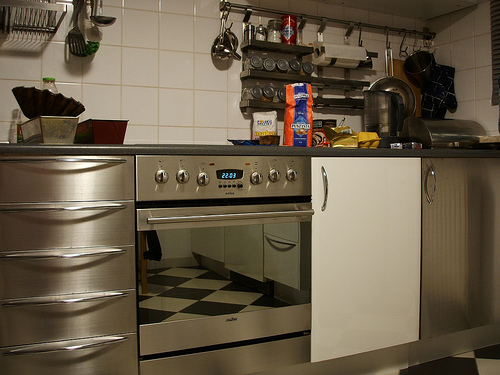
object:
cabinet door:
[420, 158, 499, 340]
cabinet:
[0, 143, 500, 375]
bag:
[283, 83, 314, 148]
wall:
[0, 0, 500, 145]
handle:
[321, 166, 328, 212]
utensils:
[89, 0, 115, 27]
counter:
[0, 143, 500, 158]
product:
[357, 130, 381, 149]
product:
[323, 126, 359, 150]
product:
[312, 129, 331, 148]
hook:
[409, 30, 421, 53]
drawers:
[0, 244, 137, 300]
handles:
[0, 291, 130, 307]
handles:
[0, 203, 127, 212]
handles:
[0, 248, 128, 261]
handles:
[0, 156, 127, 163]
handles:
[0, 335, 128, 354]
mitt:
[421, 65, 458, 120]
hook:
[428, 32, 437, 54]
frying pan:
[368, 47, 417, 120]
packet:
[227, 139, 278, 146]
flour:
[252, 110, 278, 140]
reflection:
[141, 287, 223, 304]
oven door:
[168, 282, 218, 307]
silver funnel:
[211, 31, 242, 61]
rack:
[217, 0, 437, 54]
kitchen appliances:
[210, 0, 457, 113]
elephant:
[307, 152, 428, 367]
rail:
[219, 0, 436, 40]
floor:
[460, 354, 500, 374]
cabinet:
[309, 155, 421, 364]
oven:
[135, 155, 311, 233]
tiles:
[117, 44, 199, 101]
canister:
[281, 15, 297, 45]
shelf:
[240, 69, 371, 92]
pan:
[368, 76, 416, 121]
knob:
[287, 169, 298, 182]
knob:
[268, 169, 281, 182]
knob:
[250, 171, 263, 184]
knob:
[197, 172, 210, 186]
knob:
[176, 170, 190, 184]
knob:
[155, 169, 168, 184]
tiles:
[474, 351, 500, 375]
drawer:
[0, 155, 135, 202]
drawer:
[1, 201, 136, 253]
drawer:
[0, 289, 137, 349]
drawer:
[0, 332, 138, 375]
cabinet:
[418, 156, 499, 341]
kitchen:
[0, 0, 500, 375]